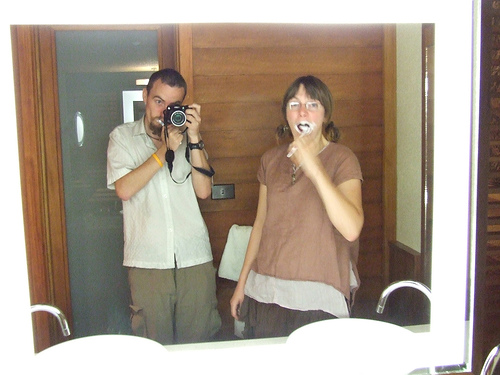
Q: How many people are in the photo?
A: Two.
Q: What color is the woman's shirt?
A: Brown.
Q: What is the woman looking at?
A: A mirror.